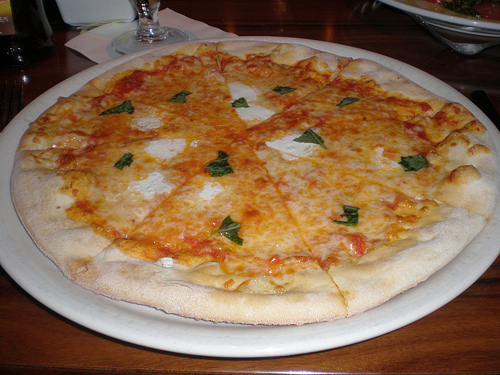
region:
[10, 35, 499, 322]
Artisan cheese pizza with basil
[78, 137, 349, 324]
Slice of cheese pizza with basil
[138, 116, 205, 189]
Melted cheese on a pizza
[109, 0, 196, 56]
Bottom of a water glass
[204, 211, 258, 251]
Basil used as a pizza topping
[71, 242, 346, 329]
Home made pizza crust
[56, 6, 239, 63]
Napkin under a glass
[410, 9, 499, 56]
Part of a fork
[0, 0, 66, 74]
Part of a bottle of olive oil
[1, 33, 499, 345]
Pizza from an old style restuarant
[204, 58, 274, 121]
orange green and white topping on pizza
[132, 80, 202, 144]
orange green and white topping on pizza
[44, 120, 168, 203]
orange green and white topping on pizza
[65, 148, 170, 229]
orange green and white topping on pizza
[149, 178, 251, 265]
orange green and white topping on pizza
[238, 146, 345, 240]
orange green and white topping on pizza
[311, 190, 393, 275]
orange green and white topping on pizza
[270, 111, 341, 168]
orange green and white topping on pizza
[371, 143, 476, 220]
orange green and white topping on pizza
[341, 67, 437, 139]
orange green and white topping on pizza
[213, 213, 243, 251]
Green herb leaf on pizza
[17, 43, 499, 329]
Large round pizza on plate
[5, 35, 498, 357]
Large white plate under pizza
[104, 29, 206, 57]
Round base of drinking glass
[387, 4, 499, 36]
Edge of white plate on table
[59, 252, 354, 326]
Light tan crust edge on pizza slice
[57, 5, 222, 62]
Small square napkin under glass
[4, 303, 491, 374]
Brown wooden edge of table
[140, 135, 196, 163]
White sauce on pizza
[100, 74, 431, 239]
Green leaves covering pizza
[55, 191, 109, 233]
orange white and green toppings on pizza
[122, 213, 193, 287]
orange white and green toppings on pizza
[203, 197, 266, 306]
orange white and green toppings on pizza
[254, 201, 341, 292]
orange white and green toppings on pizza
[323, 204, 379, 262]
orange white and green toppings on pizza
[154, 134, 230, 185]
orange white and green toppings on pizza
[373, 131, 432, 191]
orange white and green toppings on pizza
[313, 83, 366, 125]
orange white and green toppings on pizza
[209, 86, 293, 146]
orange white and green toppings on pizza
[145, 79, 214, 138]
orange white and green toppings on pizza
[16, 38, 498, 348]
light colored pizza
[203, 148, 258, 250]
greenery topping a pizza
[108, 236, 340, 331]
light dough of a pizza crust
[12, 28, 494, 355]
pizza sitting on a white plate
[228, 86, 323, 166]
white melted cheese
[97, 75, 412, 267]
red sauce with yellow cheese on top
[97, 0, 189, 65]
the base of a glass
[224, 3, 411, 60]
shiny wooden table top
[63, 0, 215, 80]
glass sitting on a white napkin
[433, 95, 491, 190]
bubbles on the crust